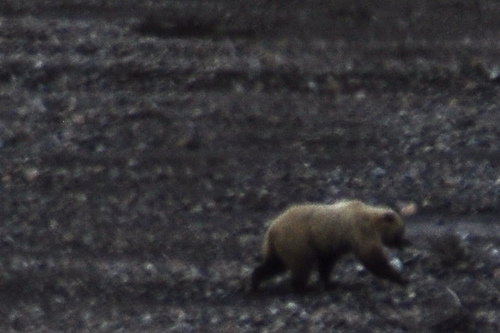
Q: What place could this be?
A: It is a field.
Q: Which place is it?
A: It is a field.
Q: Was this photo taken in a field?
A: Yes, it was taken in a field.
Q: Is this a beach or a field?
A: It is a field.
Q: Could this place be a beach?
A: No, it is a field.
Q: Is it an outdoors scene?
A: Yes, it is outdoors.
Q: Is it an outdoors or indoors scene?
A: It is outdoors.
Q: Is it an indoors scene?
A: No, it is outdoors.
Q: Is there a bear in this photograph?
A: Yes, there is a bear.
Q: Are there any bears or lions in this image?
A: Yes, there is a bear.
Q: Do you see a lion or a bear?
A: Yes, there is a bear.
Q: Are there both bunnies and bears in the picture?
A: No, there is a bear but no bunnies.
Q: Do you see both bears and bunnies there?
A: No, there is a bear but no bunnies.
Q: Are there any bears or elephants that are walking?
A: Yes, the bear is walking.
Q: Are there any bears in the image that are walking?
A: Yes, there is a bear that is walking.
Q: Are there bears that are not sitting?
A: Yes, there is a bear that is walking.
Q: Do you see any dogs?
A: No, there are no dogs.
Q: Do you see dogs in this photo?
A: No, there are no dogs.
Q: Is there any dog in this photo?
A: No, there are no dogs.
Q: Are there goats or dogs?
A: No, there are no dogs or goats.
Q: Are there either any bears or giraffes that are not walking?
A: No, there is a bear but it is walking.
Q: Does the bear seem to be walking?
A: Yes, the bear is walking.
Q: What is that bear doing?
A: The bear is walking.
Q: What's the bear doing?
A: The bear is walking.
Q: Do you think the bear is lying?
A: No, the bear is walking.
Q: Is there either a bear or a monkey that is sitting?
A: No, there is a bear but it is walking.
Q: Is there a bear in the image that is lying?
A: No, there is a bear but it is walking.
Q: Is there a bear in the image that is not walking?
A: No, there is a bear but it is walking.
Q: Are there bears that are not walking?
A: No, there is a bear but it is walking.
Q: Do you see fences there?
A: No, there are no fences.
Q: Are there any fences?
A: No, there are no fences.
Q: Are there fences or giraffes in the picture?
A: No, there are no fences or giraffes.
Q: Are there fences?
A: No, there are no fences.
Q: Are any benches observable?
A: No, there are no benches.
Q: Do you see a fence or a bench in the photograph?
A: No, there are no benches or fences.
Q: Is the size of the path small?
A: Yes, the path is small.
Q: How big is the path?
A: The path is small.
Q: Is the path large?
A: No, the path is small.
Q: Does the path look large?
A: No, the path is small.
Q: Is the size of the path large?
A: No, the path is small.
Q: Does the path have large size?
A: No, the path is small.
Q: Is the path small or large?
A: The path is small.